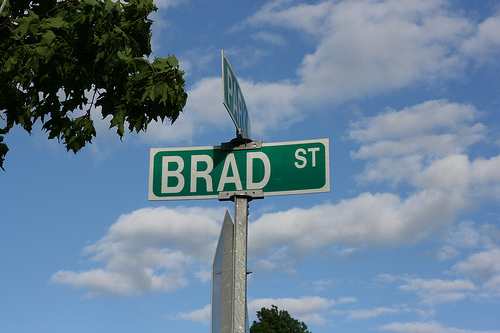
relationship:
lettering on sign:
[160, 147, 319, 194] [147, 138, 332, 200]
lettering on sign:
[226, 66, 248, 134] [221, 49, 253, 141]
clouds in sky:
[17, 0, 499, 331] [1, 1, 499, 331]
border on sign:
[148, 137, 332, 202] [147, 138, 332, 200]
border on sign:
[220, 46, 248, 141] [221, 49, 253, 141]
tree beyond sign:
[0, 1, 189, 171] [147, 138, 332, 200]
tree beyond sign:
[0, 1, 189, 171] [221, 49, 253, 141]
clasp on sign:
[216, 187, 265, 201] [147, 138, 332, 200]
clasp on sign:
[222, 141, 264, 153] [147, 138, 332, 200]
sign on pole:
[147, 138, 332, 200] [229, 194, 253, 332]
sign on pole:
[221, 49, 253, 141] [229, 194, 253, 332]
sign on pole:
[211, 208, 235, 332] [229, 194, 253, 332]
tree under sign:
[249, 304, 310, 332] [147, 138, 332, 200]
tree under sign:
[249, 304, 310, 332] [221, 49, 253, 141]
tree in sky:
[0, 1, 189, 171] [1, 1, 499, 331]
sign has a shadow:
[221, 49, 253, 141] [211, 143, 238, 165]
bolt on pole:
[245, 270, 252, 276] [229, 194, 253, 332]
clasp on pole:
[216, 187, 265, 201] [229, 194, 253, 332]